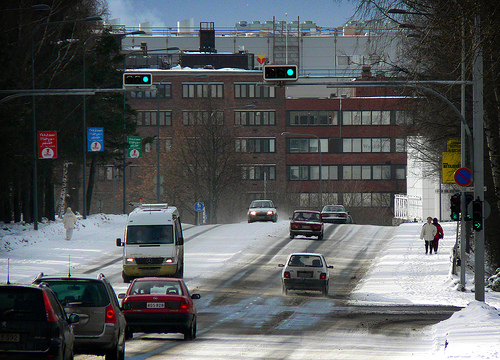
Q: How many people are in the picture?
A: Three.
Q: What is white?
A: Snow.